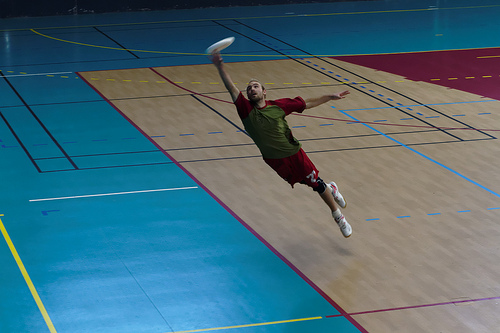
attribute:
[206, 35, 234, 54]
frisbee — white, flying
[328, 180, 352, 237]
shoes — white, red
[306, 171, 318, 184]
design — white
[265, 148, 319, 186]
shorts — red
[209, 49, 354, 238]
man — jumping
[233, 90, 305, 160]
shirt — red, green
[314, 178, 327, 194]
knee guard — black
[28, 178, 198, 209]
line — white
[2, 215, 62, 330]
line — yellow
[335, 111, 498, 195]
line — blue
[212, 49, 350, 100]
hands — out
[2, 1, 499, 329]
ground — paved